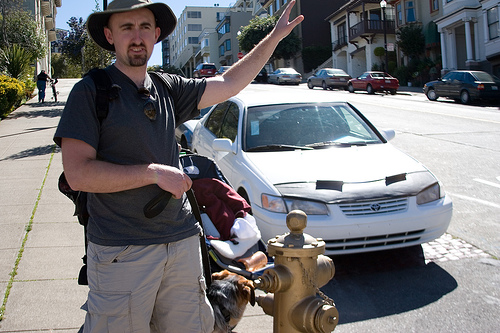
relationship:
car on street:
[187, 82, 455, 272] [170, 69, 500, 332]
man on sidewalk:
[49, 1, 310, 333] [1, 76, 309, 332]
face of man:
[111, 11, 155, 68] [49, 1, 310, 333]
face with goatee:
[111, 11, 155, 68] [125, 42, 150, 66]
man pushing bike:
[34, 67, 56, 108] [48, 75, 64, 102]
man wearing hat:
[49, 1, 310, 333] [84, 1, 178, 56]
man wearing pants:
[49, 1, 310, 333] [78, 235, 217, 332]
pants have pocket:
[78, 235, 217, 332] [79, 291, 134, 332]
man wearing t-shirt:
[49, 1, 310, 333] [52, 63, 211, 248]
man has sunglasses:
[49, 1, 310, 333] [139, 86, 159, 123]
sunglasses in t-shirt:
[139, 86, 159, 123] [52, 63, 211, 248]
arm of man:
[174, 0, 302, 120] [49, 1, 310, 333]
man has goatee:
[49, 1, 310, 333] [125, 42, 150, 66]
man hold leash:
[49, 1, 310, 333] [140, 183, 178, 216]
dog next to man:
[74, 260, 257, 332] [49, 1, 310, 333]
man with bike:
[34, 67, 56, 108] [48, 75, 64, 102]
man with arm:
[49, 1, 310, 333] [174, 0, 302, 120]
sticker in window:
[248, 118, 264, 138] [244, 99, 387, 157]